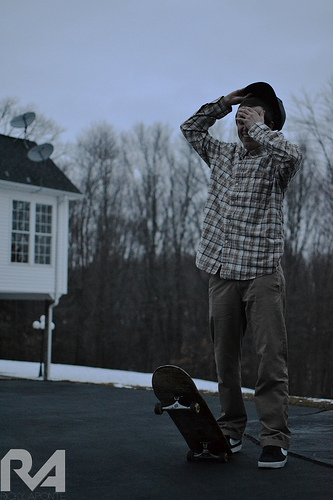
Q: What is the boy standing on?
A: A skateboard.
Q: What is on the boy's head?
A: A hat.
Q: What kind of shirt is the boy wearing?
A: A plaid flannel shirt.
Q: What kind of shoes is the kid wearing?
A: Black and white tennis shoes.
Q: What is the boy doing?
A: Wiping his forehead.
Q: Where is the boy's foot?
A: On the bottom of the skateboard.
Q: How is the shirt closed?
A: With buttons.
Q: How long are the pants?
A: Down to his feet.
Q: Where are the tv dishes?
A: On the roof.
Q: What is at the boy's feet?
A: A skateboard.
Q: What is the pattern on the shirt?
A: Plaid.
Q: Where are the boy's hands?
A: On his head and face.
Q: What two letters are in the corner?
A: RA.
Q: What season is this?
A: Winter.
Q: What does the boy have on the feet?
A: Athletic shoes.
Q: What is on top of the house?
A: Satellite dishes.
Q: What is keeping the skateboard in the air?
A: The boy's foot.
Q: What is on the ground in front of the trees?
A: Snow.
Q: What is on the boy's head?
A: A hat.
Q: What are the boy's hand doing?
A: Covering his face.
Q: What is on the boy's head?
A: A hat.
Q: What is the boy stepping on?
A: A skateboard.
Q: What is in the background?
A: Trees.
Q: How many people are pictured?
A: One.